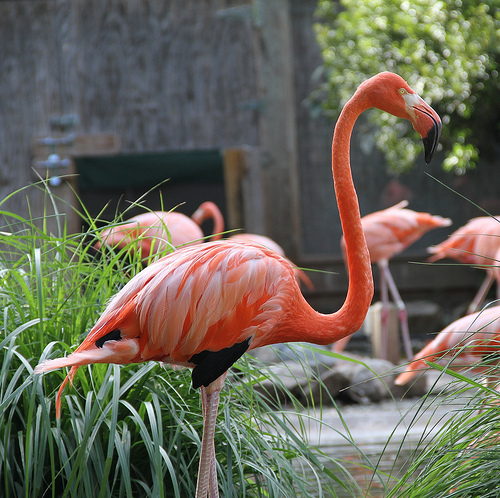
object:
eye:
[398, 87, 405, 92]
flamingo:
[93, 200, 226, 267]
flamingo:
[424, 215, 499, 315]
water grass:
[0, 166, 282, 496]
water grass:
[360, 169, 499, 496]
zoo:
[0, 0, 499, 497]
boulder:
[227, 340, 425, 410]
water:
[257, 395, 320, 436]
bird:
[33, 70, 442, 497]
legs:
[202, 389, 219, 498]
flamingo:
[331, 198, 453, 360]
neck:
[331, 100, 374, 341]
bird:
[393, 303, 499, 417]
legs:
[463, 270, 494, 314]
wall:
[0, 0, 499, 260]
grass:
[0, 361, 290, 497]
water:
[364, 388, 476, 420]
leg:
[377, 275, 389, 359]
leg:
[382, 265, 414, 360]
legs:
[194, 385, 222, 497]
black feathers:
[188, 336, 250, 390]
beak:
[420, 123, 441, 164]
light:
[49, 174, 62, 187]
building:
[0, 0, 499, 355]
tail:
[32, 335, 140, 375]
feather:
[125, 282, 147, 320]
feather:
[33, 352, 88, 377]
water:
[271, 443, 499, 497]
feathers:
[227, 270, 287, 308]